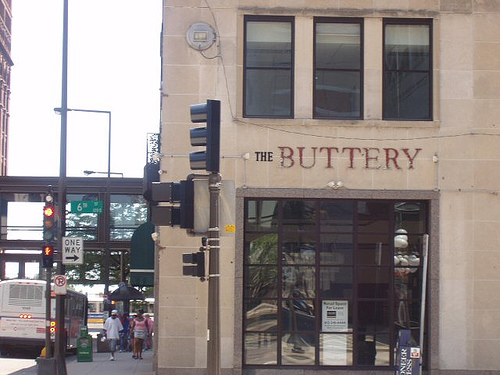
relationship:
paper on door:
[321, 300, 348, 331] [316, 263, 356, 368]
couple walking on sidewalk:
[105, 304, 147, 359] [87, 363, 144, 371]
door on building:
[232, 187, 441, 373] [156, 0, 497, 367]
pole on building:
[185, 168, 255, 372] [159, 105, 241, 359]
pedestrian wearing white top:
[104, 310, 122, 360] [102, 317, 122, 339]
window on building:
[382, 17, 436, 118] [156, 0, 497, 367]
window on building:
[312, 14, 365, 120] [156, 0, 497, 367]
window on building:
[240, 10, 294, 119] [156, 0, 497, 367]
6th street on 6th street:
[73, 200, 99, 212] [71, 200, 104, 213]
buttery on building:
[250, 146, 424, 168] [156, 0, 497, 367]